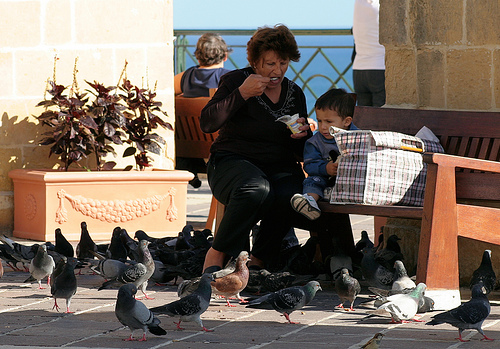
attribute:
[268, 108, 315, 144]
yogurt cup — white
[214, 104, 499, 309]
bench — wooden 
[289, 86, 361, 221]
boy — little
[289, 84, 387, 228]
boy — little 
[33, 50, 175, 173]
plants — purple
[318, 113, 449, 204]
bag — large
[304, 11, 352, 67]
ocean — blue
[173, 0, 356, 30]
sky — blue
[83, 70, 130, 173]
plants — purple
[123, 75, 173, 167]
plants — purple